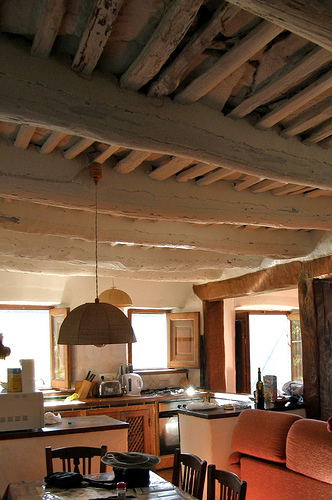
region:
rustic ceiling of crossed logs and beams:
[18, 94, 309, 295]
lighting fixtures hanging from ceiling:
[33, 169, 150, 351]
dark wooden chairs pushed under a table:
[29, 440, 250, 494]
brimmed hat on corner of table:
[97, 437, 160, 484]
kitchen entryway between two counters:
[96, 396, 223, 484]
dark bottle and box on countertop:
[244, 352, 280, 407]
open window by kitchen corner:
[116, 298, 199, 366]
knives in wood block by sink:
[55, 366, 92, 403]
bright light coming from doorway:
[239, 307, 298, 396]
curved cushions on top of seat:
[232, 395, 325, 486]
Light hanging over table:
[32, 260, 141, 369]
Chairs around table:
[145, 438, 245, 498]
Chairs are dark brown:
[169, 433, 211, 496]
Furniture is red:
[225, 385, 306, 486]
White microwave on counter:
[4, 379, 64, 449]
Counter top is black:
[67, 401, 132, 440]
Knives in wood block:
[78, 357, 95, 415]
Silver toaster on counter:
[99, 369, 140, 421]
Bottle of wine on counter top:
[253, 350, 280, 423]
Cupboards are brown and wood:
[100, 396, 159, 461]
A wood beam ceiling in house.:
[20, 115, 322, 280]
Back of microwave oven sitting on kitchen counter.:
[1, 387, 51, 438]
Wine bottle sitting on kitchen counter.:
[253, 362, 267, 406]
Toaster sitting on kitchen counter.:
[94, 379, 129, 401]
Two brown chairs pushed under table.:
[169, 447, 255, 499]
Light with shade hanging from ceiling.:
[53, 180, 139, 356]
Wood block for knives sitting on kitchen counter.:
[76, 364, 103, 401]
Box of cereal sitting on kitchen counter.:
[262, 374, 280, 404]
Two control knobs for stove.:
[170, 400, 188, 413]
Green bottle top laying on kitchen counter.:
[62, 419, 76, 428]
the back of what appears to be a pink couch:
[227, 409, 327, 497]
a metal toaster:
[94, 373, 123, 399]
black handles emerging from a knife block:
[75, 366, 94, 400]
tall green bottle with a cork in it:
[249, 359, 267, 409]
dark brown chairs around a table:
[30, 438, 243, 492]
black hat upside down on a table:
[91, 440, 163, 490]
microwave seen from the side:
[0, 387, 44, 433]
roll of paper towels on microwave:
[18, 352, 41, 402]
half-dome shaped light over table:
[57, 169, 138, 497]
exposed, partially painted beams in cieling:
[0, 4, 326, 274]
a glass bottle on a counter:
[253, 366, 264, 411]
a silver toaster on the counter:
[90, 376, 125, 399]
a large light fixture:
[55, 299, 139, 348]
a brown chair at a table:
[168, 445, 207, 498]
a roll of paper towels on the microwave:
[17, 355, 35, 393]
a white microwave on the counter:
[0, 387, 48, 440]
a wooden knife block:
[74, 377, 92, 401]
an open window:
[0, 306, 72, 393]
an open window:
[125, 306, 204, 375]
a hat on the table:
[104, 447, 159, 487]